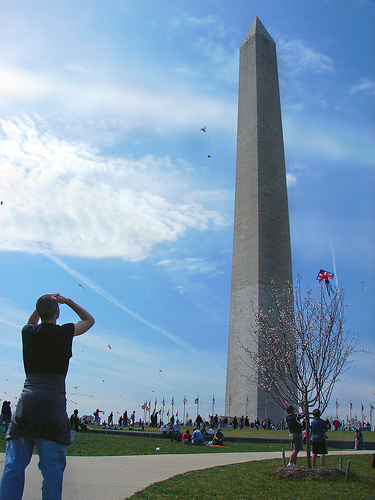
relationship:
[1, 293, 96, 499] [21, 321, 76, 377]
man wearing shirt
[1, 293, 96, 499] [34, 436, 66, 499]
man has leg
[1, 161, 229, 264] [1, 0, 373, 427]
cloud in sky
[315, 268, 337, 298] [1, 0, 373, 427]
kite in sky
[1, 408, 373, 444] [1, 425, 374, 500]
crowd on top of grass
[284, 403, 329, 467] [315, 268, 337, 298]
people are flying kite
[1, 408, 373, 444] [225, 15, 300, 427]
crowd at base of monument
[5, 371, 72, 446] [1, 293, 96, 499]
sweatshirt tied around man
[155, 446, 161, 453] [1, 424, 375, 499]
object on ground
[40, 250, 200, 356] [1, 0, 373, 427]
streak in sky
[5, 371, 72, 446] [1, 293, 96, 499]
sweatshirt around man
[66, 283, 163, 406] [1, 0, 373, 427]
kites in sky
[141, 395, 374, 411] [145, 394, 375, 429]
flags are on poles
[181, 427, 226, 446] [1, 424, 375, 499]
people sitting on ground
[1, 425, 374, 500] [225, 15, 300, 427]
grass around monument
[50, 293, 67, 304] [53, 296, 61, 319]
hands covering face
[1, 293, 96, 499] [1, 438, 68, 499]
man wearing jeans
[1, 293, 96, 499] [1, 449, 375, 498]
man near walkway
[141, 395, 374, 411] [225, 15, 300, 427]
flags surround monument